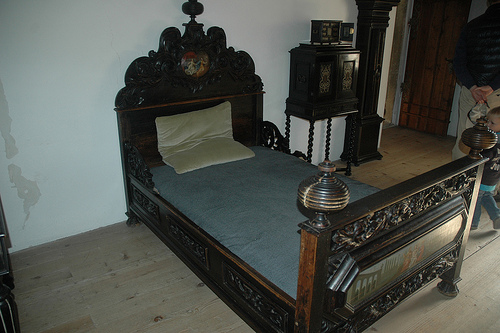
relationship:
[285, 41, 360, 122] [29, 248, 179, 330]
chest on floor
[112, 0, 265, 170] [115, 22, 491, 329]
headboard of bed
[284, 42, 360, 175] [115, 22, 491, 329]
stand next to bed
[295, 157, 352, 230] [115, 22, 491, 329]
pole of bed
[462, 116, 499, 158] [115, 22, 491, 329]
pole of bed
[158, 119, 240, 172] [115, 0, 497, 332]
pillow on bed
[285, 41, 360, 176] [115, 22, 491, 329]
chest beside bed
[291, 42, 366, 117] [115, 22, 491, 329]
cabinet beside bed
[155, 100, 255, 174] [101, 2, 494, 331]
pillow on bed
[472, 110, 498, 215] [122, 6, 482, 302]
child beside bed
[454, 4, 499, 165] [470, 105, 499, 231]
person beside child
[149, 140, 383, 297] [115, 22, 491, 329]
mattress on bed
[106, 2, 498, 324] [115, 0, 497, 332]
frame of bed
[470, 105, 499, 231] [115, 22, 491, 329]
child near bed